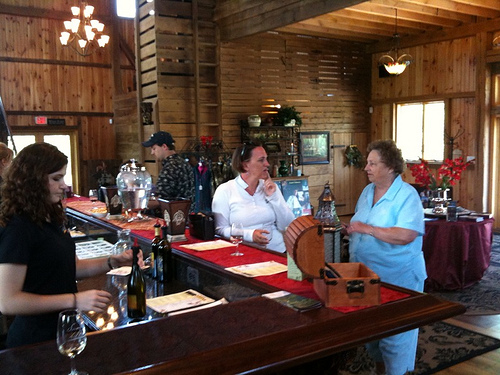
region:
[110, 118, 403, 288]
people at the bar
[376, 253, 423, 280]
the shirt is blue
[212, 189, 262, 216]
the shirt is white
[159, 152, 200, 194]
pattern on teh shirt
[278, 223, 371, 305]
trunk on the counter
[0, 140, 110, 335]
woman making a drink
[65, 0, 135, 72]
light on the ceiling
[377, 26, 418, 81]
light on the ceiling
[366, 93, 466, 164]
the window is bright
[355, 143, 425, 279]
a lady standing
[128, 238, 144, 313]
a bottle of alcohol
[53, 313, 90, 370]
a glass on the counter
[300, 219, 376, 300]
an open box on the counter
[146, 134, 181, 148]
a cap on the head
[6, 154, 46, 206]
the hair of a lady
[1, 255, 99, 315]
the hand of a lady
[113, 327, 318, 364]
a wooden counter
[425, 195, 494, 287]
a table the is set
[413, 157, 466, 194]
flowers on the table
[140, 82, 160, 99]
brown board on wall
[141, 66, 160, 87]
brown board on wall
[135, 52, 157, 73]
brown board on wall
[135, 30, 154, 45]
brown board on wall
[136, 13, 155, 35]
brown board on wall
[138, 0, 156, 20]
brown board on wall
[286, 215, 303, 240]
brown board on wall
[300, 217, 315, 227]
brown board on wall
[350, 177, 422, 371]
the woman is wearing light blue.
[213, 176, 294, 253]
the woman has on white shirt.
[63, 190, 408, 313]
red runner on counter top.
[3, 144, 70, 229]
the woman's hair is brown.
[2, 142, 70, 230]
the woman has wavy hair.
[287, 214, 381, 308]
wooden box on counter.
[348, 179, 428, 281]
light blue shirt on woman.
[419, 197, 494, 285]
the table is round.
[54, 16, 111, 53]
chandelier in background.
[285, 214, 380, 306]
a small wooden treasure chest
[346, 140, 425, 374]
a woman wearing a light blue outfit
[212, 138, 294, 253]
a woman wearing a white shirt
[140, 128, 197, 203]
a man wearing a black baseball hat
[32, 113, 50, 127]
an exit sign hanging over a door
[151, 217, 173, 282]
two bottles of alcohol behind the bar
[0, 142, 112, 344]
a woman wearing a black shirt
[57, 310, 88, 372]
a wine glass sitting on the bar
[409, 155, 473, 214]
a silver vase with red flowers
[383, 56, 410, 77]
a lovely light fixture